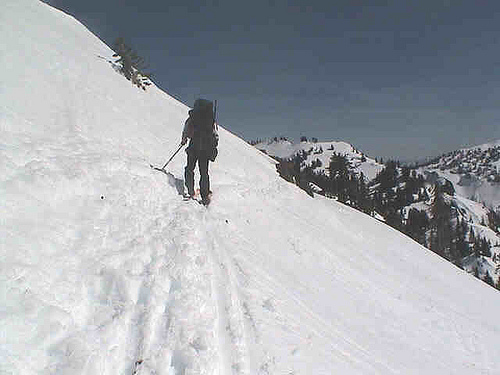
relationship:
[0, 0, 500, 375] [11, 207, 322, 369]
snow covering ground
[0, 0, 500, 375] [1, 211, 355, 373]
snow covering ground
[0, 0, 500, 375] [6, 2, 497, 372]
snow covering ground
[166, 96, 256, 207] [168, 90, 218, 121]
man carrying backpack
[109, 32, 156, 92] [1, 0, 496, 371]
branch on hill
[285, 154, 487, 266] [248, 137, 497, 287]
pines on mountain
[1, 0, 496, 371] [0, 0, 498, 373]
hill covered with snow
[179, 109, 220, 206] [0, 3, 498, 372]
man on mountain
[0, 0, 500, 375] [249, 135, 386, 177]
mountain covered with snow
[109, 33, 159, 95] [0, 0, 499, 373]
tree on mountainside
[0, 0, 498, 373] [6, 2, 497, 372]
snow on ground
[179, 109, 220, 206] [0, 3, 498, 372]
man skiing up mountain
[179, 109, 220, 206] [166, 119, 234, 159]
man wearing backpack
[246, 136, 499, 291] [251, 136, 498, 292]
trees on mountain top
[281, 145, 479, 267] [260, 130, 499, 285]
trees on mountain top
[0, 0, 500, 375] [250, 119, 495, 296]
snow on mountain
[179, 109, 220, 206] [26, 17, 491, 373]
man walking in snow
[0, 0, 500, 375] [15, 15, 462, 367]
mountain covered with snow